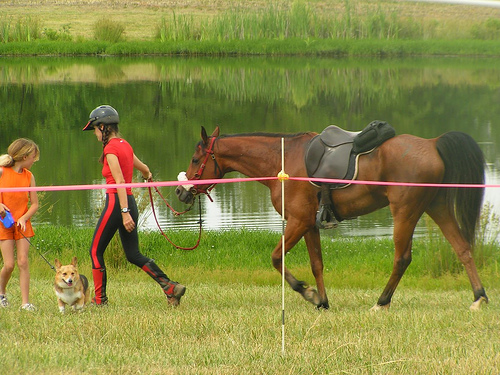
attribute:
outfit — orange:
[0, 161, 36, 237]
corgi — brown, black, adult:
[48, 253, 93, 313]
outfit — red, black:
[86, 137, 187, 308]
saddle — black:
[302, 122, 400, 226]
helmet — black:
[79, 101, 120, 130]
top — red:
[104, 134, 139, 193]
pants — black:
[90, 192, 171, 279]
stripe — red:
[85, 188, 116, 264]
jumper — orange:
[1, 167, 35, 244]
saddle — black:
[301, 120, 395, 186]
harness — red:
[300, 120, 393, 194]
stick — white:
[277, 133, 290, 353]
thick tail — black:
[439, 128, 482, 248]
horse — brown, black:
[171, 111, 492, 319]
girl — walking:
[4, 126, 41, 311]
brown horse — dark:
[176, 101, 489, 316]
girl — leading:
[64, 91, 194, 308]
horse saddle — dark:
[302, 114, 388, 195]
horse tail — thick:
[438, 128, 494, 236]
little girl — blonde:
[2, 140, 46, 318]